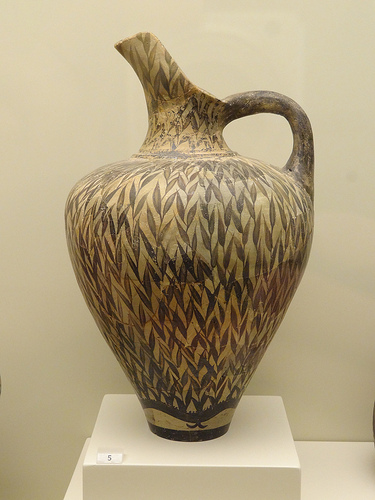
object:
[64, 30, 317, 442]
artifact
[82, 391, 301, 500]
display stand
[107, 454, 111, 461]
number 5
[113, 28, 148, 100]
spout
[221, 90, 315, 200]
handle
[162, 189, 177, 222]
brown leaves pattern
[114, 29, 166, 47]
top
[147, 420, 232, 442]
base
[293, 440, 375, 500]
area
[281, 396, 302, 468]
edge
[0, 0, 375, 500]
wall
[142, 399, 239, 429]
brown trim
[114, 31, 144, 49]
chip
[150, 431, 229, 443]
small base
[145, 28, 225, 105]
curved lip